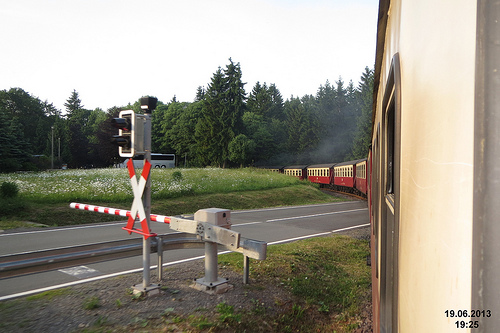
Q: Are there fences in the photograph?
A: No, there are no fences.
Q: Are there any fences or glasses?
A: No, there are no fences or glasses.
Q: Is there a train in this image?
A: Yes, there is a train.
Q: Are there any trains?
A: Yes, there is a train.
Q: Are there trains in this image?
A: Yes, there is a train.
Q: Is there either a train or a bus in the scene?
A: Yes, there is a train.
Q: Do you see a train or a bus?
A: Yes, there is a train.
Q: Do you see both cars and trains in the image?
A: Yes, there are both a train and a car.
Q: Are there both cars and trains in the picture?
A: Yes, there are both a train and a car.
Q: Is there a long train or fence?
A: Yes, there is a long train.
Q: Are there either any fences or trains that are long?
A: Yes, the train is long.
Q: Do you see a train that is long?
A: Yes, there is a long train.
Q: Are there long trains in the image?
A: Yes, there is a long train.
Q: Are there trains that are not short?
A: Yes, there is a long train.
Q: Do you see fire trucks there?
A: No, there are no fire trucks.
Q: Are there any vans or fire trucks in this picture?
A: No, there are no fire trucks or vans.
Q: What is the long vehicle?
A: The vehicle is a train.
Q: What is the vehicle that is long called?
A: The vehicle is a train.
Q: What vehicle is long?
A: The vehicle is a train.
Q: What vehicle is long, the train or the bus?
A: The train is long.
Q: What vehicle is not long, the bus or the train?
A: The bus is not long.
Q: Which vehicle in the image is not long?
A: The vehicle is a bus.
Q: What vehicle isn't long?
A: The vehicle is a bus.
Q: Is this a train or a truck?
A: This is a train.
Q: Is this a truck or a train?
A: This is a train.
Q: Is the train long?
A: Yes, the train is long.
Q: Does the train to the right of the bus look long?
A: Yes, the train is long.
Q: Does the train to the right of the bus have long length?
A: Yes, the train is long.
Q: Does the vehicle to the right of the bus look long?
A: Yes, the train is long.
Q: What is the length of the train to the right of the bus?
A: The train is long.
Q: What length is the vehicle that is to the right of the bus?
A: The train is long.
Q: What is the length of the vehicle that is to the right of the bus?
A: The train is long.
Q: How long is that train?
A: The train is long.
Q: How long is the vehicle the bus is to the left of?
A: The train is long.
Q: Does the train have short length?
A: No, the train is long.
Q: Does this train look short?
A: No, the train is long.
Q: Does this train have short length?
A: No, the train is long.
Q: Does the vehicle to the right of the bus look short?
A: No, the train is long.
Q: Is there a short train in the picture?
A: No, there is a train but it is long.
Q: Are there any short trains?
A: No, there is a train but it is long.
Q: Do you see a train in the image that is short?
A: No, there is a train but it is long.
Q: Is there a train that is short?
A: No, there is a train but it is long.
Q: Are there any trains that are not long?
A: No, there is a train but it is long.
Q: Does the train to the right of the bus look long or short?
A: The train is long.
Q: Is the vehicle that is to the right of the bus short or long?
A: The train is long.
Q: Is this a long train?
A: Yes, this is a long train.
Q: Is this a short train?
A: No, this is a long train.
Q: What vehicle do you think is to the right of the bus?
A: The vehicle is a train.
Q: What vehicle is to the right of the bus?
A: The vehicle is a train.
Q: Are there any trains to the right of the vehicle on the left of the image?
A: Yes, there is a train to the right of the bus.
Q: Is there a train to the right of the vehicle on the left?
A: Yes, there is a train to the right of the bus.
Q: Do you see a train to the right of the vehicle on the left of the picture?
A: Yes, there is a train to the right of the bus.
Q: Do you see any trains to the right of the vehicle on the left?
A: Yes, there is a train to the right of the bus.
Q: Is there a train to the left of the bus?
A: No, the train is to the right of the bus.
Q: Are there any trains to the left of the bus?
A: No, the train is to the right of the bus.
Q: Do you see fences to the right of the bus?
A: No, there is a train to the right of the bus.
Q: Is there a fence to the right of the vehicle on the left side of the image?
A: No, there is a train to the right of the bus.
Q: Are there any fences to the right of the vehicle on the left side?
A: No, there is a train to the right of the bus.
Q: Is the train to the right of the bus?
A: Yes, the train is to the right of the bus.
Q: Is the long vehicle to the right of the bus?
A: Yes, the train is to the right of the bus.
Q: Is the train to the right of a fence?
A: No, the train is to the right of the bus.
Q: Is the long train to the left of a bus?
A: No, the train is to the right of a bus.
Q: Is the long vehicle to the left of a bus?
A: No, the train is to the right of a bus.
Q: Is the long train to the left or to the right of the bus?
A: The train is to the right of the bus.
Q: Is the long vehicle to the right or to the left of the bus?
A: The train is to the right of the bus.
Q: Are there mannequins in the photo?
A: No, there are no mannequins.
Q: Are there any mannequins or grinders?
A: No, there are no mannequins or grinders.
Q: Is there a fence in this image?
A: No, there are no fences.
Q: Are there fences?
A: No, there are no fences.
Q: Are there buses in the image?
A: Yes, there is a bus.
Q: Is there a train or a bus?
A: Yes, there is a bus.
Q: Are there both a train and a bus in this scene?
A: Yes, there are both a bus and a train.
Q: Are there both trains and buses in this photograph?
A: Yes, there are both a bus and a train.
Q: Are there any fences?
A: No, there are no fences.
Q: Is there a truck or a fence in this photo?
A: No, there are no fences or trucks.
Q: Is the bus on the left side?
A: Yes, the bus is on the left of the image.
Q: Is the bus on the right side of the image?
A: No, the bus is on the left of the image.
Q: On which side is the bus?
A: The bus is on the left of the image.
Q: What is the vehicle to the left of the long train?
A: The vehicle is a bus.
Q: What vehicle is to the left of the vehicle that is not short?
A: The vehicle is a bus.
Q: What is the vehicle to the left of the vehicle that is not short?
A: The vehicle is a bus.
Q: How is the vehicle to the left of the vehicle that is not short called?
A: The vehicle is a bus.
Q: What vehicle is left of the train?
A: The vehicle is a bus.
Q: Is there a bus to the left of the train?
A: Yes, there is a bus to the left of the train.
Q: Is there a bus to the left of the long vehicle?
A: Yes, there is a bus to the left of the train.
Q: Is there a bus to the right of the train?
A: No, the bus is to the left of the train.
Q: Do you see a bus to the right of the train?
A: No, the bus is to the left of the train.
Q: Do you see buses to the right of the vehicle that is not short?
A: No, the bus is to the left of the train.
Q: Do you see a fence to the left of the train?
A: No, there is a bus to the left of the train.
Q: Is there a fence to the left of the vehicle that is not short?
A: No, there is a bus to the left of the train.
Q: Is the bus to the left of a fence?
A: No, the bus is to the left of the train.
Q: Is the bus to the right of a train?
A: No, the bus is to the left of a train.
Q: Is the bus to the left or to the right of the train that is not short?
A: The bus is to the left of the train.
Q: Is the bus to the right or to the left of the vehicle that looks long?
A: The bus is to the left of the train.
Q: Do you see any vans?
A: No, there are no vans.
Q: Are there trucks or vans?
A: No, there are no vans or trucks.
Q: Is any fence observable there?
A: No, there are no fences.